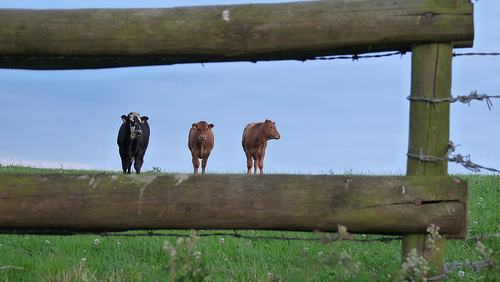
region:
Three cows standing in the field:
[102, 106, 299, 176]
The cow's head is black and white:
[119, 109, 150, 141]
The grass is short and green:
[35, 238, 402, 278]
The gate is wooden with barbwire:
[14, 0, 476, 278]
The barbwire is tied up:
[440, 86, 499, 111]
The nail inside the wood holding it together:
[416, 3, 443, 25]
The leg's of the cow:
[190, 154, 214, 175]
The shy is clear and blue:
[19, 70, 396, 108]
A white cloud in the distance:
[4, 146, 101, 171]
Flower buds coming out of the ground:
[155, 220, 474, 278]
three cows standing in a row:
[107, 100, 290, 176]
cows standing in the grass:
[103, 101, 286, 172]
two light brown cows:
[179, 107, 294, 172]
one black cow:
[102, 102, 165, 172]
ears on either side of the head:
[187, 118, 217, 133]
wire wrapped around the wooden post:
[408, 148, 499, 177]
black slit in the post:
[408, 193, 463, 210]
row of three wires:
[416, 39, 499, 184]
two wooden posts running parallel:
[0, 0, 475, 234]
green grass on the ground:
[2, 155, 499, 278]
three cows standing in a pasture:
[115, 111, 281, 173]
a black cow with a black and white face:
[117, 113, 149, 173]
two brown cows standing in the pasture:
[186, 118, 281, 172]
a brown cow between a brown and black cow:
[187, 118, 214, 175]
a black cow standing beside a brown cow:
[116, 111, 214, 173]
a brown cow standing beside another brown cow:
[185, 119, 281, 171]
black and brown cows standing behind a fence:
[117, 110, 282, 170]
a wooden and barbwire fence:
[0, 0, 467, 277]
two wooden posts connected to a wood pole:
[1, 3, 470, 237]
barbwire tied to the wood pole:
[405, 50, 499, 172]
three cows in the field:
[97, 100, 321, 210]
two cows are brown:
[186, 107, 302, 166]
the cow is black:
[104, 90, 194, 181]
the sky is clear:
[298, 89, 369, 164]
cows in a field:
[46, 20, 474, 270]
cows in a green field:
[4, 7, 469, 279]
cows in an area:
[64, 44, 495, 278]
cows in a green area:
[3, 8, 451, 279]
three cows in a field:
[37, 38, 465, 279]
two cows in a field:
[50, 23, 497, 277]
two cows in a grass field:
[25, 29, 387, 279]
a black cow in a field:
[58, 53, 355, 235]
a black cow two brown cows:
[40, 68, 455, 280]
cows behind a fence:
[5, 1, 496, 278]